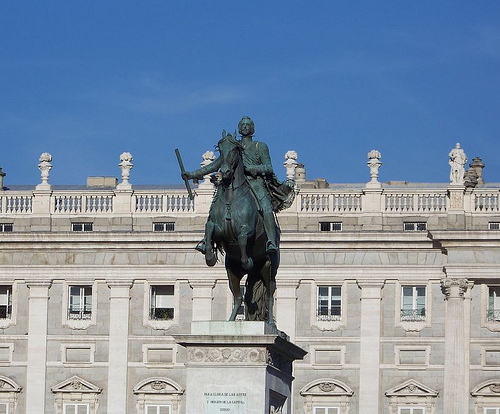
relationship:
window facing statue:
[0, 287, 13, 324] [174, 115, 294, 323]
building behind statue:
[0, 140, 498, 410] [174, 115, 294, 323]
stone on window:
[300, 377, 352, 395] [311, 403, 341, 412]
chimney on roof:
[468, 156, 484, 183] [4, 143, 493, 235]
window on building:
[67, 285, 96, 317] [0, 140, 498, 410]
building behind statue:
[0, 140, 498, 410] [168, 112, 302, 322]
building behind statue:
[0, 140, 498, 410] [150, 82, 337, 347]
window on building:
[309, 282, 351, 326] [0, 140, 498, 410]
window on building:
[392, 276, 431, 331] [0, 140, 498, 410]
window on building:
[477, 278, 498, 327] [0, 140, 498, 410]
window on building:
[227, 281, 248, 317] [0, 140, 498, 410]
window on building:
[316, 213, 347, 233] [0, 140, 498, 410]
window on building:
[483, 213, 498, 227] [0, 140, 498, 410]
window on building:
[404, 209, 429, 234] [0, 140, 498, 410]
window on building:
[146, 216, 186, 235] [0, 140, 498, 410]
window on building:
[67, 220, 95, 236] [0, 140, 498, 410]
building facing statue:
[0, 140, 498, 410] [182, 107, 301, 337]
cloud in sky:
[167, 72, 257, 109] [7, 7, 488, 108]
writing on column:
[183, 359, 268, 411] [168, 334, 297, 412]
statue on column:
[174, 115, 294, 323] [168, 334, 297, 412]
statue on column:
[174, 115, 294, 323] [341, 129, 395, 411]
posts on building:
[18, 134, 487, 185] [0, 140, 498, 410]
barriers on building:
[9, 193, 499, 213] [0, 140, 498, 410]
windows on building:
[300, 248, 447, 333] [0, 140, 498, 410]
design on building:
[4, 338, 499, 376] [0, 140, 498, 410]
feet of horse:
[199, 245, 220, 265] [211, 134, 266, 322]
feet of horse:
[238, 253, 254, 269] [211, 134, 266, 322]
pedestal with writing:
[169, 315, 303, 411] [183, 359, 268, 411]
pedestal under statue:
[169, 315, 303, 411] [174, 115, 294, 323]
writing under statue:
[183, 359, 268, 411] [174, 115, 294, 323]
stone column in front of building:
[439, 275, 474, 413] [0, 140, 498, 410]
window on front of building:
[67, 285, 96, 317] [0, 140, 498, 410]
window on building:
[137, 277, 192, 333] [0, 140, 498, 410]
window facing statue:
[313, 279, 343, 321] [168, 112, 302, 322]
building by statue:
[0, 140, 498, 410] [174, 115, 294, 323]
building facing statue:
[0, 140, 498, 410] [195, 120, 295, 317]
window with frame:
[309, 282, 351, 326] [307, 280, 348, 329]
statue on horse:
[174, 115, 294, 323] [194, 128, 284, 323]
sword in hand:
[172, 146, 197, 203] [177, 168, 196, 187]